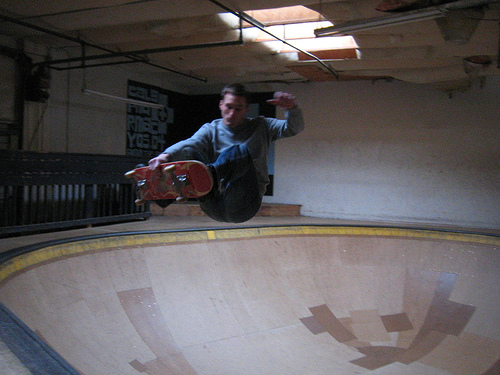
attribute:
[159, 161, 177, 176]
wheel — white 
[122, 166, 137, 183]
wheel — white 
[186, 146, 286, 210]
jeans — blue 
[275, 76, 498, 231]
brick wall — white 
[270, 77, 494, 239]
wall — white 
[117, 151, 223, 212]
skateboard — metal , silver 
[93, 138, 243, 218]
skateboard — red 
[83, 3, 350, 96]
pipes — silver 